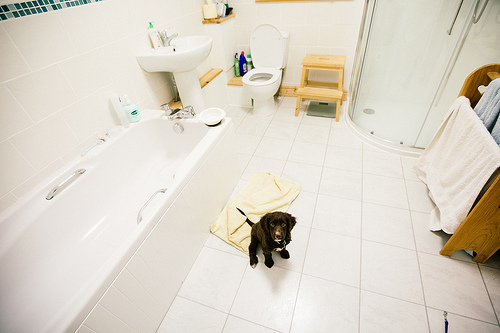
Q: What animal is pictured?
A: A puppy.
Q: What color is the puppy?
A: Brown.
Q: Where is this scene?
A: The bathroom.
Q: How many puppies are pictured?
A: One.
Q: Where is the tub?
A: To the left of the puppy.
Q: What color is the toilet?
A: White.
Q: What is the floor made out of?
A: Tile.